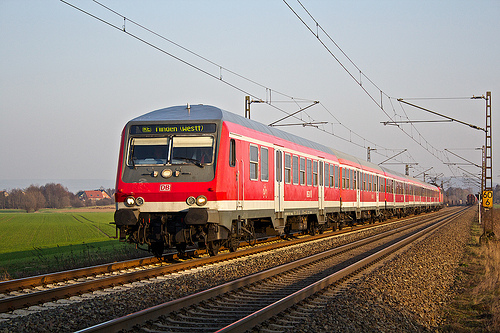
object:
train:
[110, 104, 479, 260]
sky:
[2, 16, 83, 102]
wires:
[63, 0, 277, 109]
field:
[2, 206, 101, 249]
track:
[74, 236, 383, 332]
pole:
[480, 92, 494, 233]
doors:
[274, 149, 285, 212]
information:
[142, 125, 204, 133]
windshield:
[128, 136, 217, 165]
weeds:
[0, 245, 63, 272]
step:
[270, 217, 287, 234]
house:
[75, 190, 112, 203]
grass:
[445, 211, 488, 330]